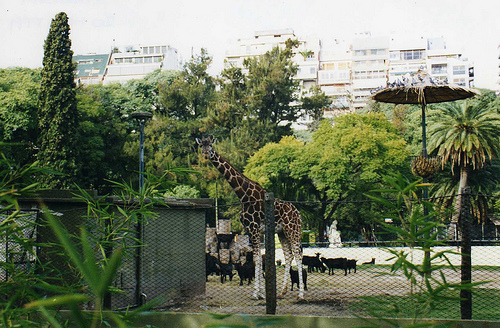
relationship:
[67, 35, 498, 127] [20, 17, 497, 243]
building behind trees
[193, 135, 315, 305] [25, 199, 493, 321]
giraffe behind fence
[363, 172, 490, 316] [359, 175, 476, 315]
leaves with leaves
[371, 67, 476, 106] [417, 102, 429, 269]
umbrella on pole